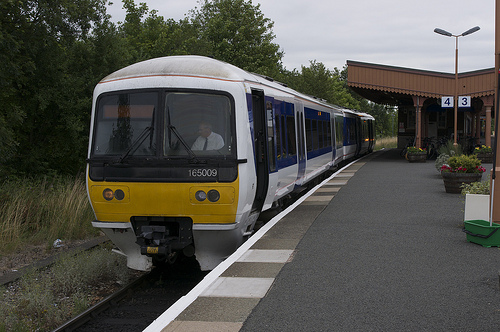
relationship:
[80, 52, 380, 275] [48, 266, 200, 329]
train sitting on track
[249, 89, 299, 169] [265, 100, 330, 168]
window has a dark blue window trim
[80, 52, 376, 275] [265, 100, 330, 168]
train has a dark blue window trim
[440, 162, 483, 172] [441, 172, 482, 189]
flowers in barrel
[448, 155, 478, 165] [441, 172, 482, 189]
greenery in barrel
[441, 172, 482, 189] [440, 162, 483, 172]
barrel holding flowers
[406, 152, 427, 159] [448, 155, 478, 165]
barrel holding greenery